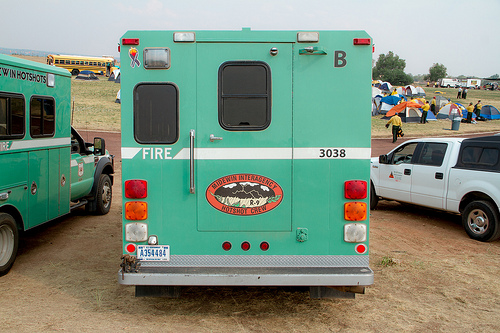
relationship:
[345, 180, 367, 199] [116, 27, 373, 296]
light on ambulance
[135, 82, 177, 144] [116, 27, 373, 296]
window on ambulance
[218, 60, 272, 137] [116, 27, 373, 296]
door window on ambulance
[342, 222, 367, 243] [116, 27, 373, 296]
light on ambulance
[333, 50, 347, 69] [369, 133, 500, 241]
b on car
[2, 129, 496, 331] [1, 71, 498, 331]
dirt on ground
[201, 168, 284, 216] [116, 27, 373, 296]
logo on ambulance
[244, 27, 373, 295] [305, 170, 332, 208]
part of truck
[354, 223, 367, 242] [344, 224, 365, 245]
part of light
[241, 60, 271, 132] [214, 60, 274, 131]
part of window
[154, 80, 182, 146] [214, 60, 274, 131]
part of window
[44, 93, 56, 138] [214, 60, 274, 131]
part of window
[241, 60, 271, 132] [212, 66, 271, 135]
part of window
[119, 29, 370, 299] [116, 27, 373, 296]
back of ambulance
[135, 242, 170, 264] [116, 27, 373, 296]
license plate on ambulance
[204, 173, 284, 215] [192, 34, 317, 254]
design on door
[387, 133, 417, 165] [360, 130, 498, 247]
window on car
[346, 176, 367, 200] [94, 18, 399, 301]
light on car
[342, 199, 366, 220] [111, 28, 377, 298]
light on car